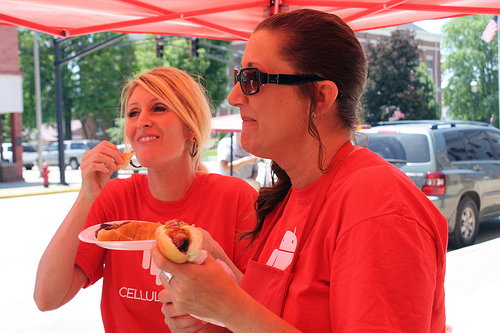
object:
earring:
[129, 150, 144, 168]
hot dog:
[94, 220, 162, 242]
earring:
[310, 112, 317, 119]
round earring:
[128, 150, 146, 168]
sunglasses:
[233, 66, 322, 95]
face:
[226, 29, 295, 152]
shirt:
[225, 146, 448, 332]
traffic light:
[156, 33, 164, 58]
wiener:
[171, 233, 186, 245]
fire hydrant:
[40, 161, 49, 187]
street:
[0, 189, 107, 332]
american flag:
[479, 15, 498, 44]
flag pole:
[496, 12, 499, 104]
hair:
[119, 66, 210, 176]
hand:
[149, 241, 245, 319]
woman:
[150, 8, 447, 332]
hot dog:
[154, 217, 206, 264]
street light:
[190, 35, 199, 59]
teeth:
[138, 135, 160, 142]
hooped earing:
[186, 136, 200, 158]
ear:
[187, 129, 195, 143]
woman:
[31, 65, 260, 333]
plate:
[77, 219, 158, 250]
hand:
[80, 139, 126, 196]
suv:
[350, 119, 499, 250]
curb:
[444, 237, 499, 332]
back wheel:
[446, 195, 480, 249]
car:
[352, 120, 499, 249]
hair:
[235, 8, 369, 251]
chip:
[117, 150, 135, 168]